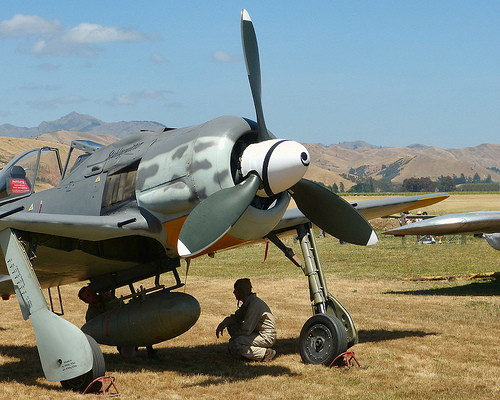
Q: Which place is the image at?
A: It is at the field.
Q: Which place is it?
A: It is a field.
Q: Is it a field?
A: Yes, it is a field.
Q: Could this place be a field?
A: Yes, it is a field.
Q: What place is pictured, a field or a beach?
A: It is a field.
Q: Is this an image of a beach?
A: No, the picture is showing a field.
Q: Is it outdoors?
A: Yes, it is outdoors.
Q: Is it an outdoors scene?
A: Yes, it is outdoors.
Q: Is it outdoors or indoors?
A: It is outdoors.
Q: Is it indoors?
A: No, it is outdoors.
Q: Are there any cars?
A: No, there are no cars.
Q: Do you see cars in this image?
A: No, there are no cars.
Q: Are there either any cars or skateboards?
A: No, there are no cars or skateboards.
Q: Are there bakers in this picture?
A: No, there are no bakers.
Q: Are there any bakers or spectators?
A: No, there are no bakers or spectators.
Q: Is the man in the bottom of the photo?
A: Yes, the man is in the bottom of the image.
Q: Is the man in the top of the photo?
A: No, the man is in the bottom of the image.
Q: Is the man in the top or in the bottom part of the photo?
A: The man is in the bottom of the image.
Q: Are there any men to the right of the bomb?
A: Yes, there is a man to the right of the bomb.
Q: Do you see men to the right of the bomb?
A: Yes, there is a man to the right of the bomb.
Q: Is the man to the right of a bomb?
A: Yes, the man is to the right of a bomb.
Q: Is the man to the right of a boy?
A: No, the man is to the right of a bomb.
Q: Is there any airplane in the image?
A: Yes, there is an airplane.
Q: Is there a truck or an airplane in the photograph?
A: Yes, there is an airplane.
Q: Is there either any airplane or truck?
A: Yes, there is an airplane.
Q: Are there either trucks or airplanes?
A: Yes, there is an airplane.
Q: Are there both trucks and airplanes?
A: No, there is an airplane but no trucks.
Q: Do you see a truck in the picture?
A: No, there are no trucks.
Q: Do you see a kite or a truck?
A: No, there are no trucks or kites.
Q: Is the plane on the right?
A: Yes, the plane is on the right of the image.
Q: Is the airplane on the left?
A: No, the airplane is on the right of the image.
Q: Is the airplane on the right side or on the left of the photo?
A: The airplane is on the right of the image.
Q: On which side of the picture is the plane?
A: The plane is on the right of the image.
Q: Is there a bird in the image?
A: No, there are no birds.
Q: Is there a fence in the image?
A: No, there are no fences.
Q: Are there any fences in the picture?
A: No, there are no fences.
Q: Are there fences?
A: No, there are no fences.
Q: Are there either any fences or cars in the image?
A: No, there are no fences or cars.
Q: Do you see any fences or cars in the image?
A: No, there are no fences or cars.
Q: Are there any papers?
A: No, there are no papers.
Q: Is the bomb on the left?
A: Yes, the bomb is on the left of the image.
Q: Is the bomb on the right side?
A: No, the bomb is on the left of the image.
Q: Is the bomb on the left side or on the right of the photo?
A: The bomb is on the left of the image.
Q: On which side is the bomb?
A: The bomb is on the left of the image.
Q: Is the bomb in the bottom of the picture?
A: Yes, the bomb is in the bottom of the image.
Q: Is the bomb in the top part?
A: No, the bomb is in the bottom of the image.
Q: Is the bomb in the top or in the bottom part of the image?
A: The bomb is in the bottom of the image.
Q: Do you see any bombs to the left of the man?
A: Yes, there is a bomb to the left of the man.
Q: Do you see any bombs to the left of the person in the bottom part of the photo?
A: Yes, there is a bomb to the left of the man.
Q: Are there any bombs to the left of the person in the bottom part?
A: Yes, there is a bomb to the left of the man.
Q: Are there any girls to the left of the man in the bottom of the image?
A: No, there is a bomb to the left of the man.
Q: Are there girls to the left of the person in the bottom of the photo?
A: No, there is a bomb to the left of the man.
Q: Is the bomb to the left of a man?
A: Yes, the bomb is to the left of a man.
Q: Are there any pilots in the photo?
A: No, there are no pilots.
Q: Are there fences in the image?
A: No, there are no fences.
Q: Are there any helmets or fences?
A: No, there are no fences or helmets.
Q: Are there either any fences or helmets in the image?
A: No, there are no fences or helmets.